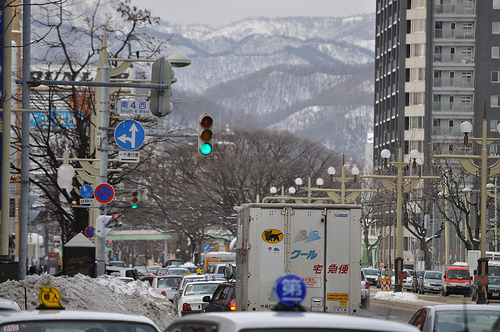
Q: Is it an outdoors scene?
A: Yes, it is outdoors.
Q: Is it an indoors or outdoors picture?
A: It is outdoors.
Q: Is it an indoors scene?
A: No, it is outdoors.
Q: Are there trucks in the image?
A: Yes, there is a truck.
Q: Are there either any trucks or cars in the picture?
A: Yes, there is a truck.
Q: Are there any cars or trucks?
A: Yes, there is a truck.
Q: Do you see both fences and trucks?
A: No, there is a truck but no fences.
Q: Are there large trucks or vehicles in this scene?
A: Yes, there is a large truck.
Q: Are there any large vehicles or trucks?
A: Yes, there is a large truck.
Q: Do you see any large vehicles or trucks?
A: Yes, there is a large truck.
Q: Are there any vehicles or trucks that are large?
A: Yes, the truck is large.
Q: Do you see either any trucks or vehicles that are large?
A: Yes, the truck is large.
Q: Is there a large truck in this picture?
A: Yes, there is a large truck.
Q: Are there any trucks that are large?
A: Yes, there is a truck that is large.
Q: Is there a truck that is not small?
A: Yes, there is a large truck.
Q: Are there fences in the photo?
A: No, there are no fences.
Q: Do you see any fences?
A: No, there are no fences.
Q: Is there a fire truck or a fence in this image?
A: No, there are no fences or fire trucks.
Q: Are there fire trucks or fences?
A: No, there are no fences or fire trucks.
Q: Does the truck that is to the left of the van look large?
A: Yes, the truck is large.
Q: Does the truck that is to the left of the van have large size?
A: Yes, the truck is large.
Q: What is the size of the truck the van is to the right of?
A: The truck is large.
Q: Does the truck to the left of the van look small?
A: No, the truck is large.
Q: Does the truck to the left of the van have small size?
A: No, the truck is large.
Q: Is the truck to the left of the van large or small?
A: The truck is large.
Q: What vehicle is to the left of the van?
A: The vehicle is a truck.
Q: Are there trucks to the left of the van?
A: Yes, there is a truck to the left of the van.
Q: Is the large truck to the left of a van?
A: Yes, the truck is to the left of a van.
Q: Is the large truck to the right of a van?
A: No, the truck is to the left of a van.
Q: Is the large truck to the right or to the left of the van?
A: The truck is to the left of the van.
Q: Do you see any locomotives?
A: No, there are no locomotives.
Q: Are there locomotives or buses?
A: No, there are no locomotives or buses.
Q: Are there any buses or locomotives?
A: No, there are no locomotives or buses.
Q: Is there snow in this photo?
A: Yes, there is snow.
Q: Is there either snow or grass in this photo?
A: Yes, there is snow.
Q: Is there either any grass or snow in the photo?
A: Yes, there is snow.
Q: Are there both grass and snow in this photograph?
A: No, there is snow but no grass.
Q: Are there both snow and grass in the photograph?
A: No, there is snow but no grass.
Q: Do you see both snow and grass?
A: No, there is snow but no grass.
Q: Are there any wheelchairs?
A: No, there are no wheelchairs.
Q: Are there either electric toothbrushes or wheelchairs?
A: No, there are no wheelchairs or electric toothbrushes.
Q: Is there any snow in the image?
A: Yes, there is snow.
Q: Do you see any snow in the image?
A: Yes, there is snow.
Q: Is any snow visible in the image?
A: Yes, there is snow.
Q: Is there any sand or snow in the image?
A: Yes, there is snow.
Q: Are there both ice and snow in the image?
A: No, there is snow but no ice.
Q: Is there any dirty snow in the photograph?
A: Yes, there is dirty snow.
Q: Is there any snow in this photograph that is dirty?
A: Yes, there is snow that is dirty.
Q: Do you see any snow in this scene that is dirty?
A: Yes, there is snow that is dirty.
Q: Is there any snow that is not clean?
A: Yes, there is dirty snow.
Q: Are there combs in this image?
A: No, there are no combs.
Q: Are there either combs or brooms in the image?
A: No, there are no combs or brooms.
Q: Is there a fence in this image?
A: No, there are no fences.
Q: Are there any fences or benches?
A: No, there are no fences or benches.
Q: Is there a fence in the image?
A: No, there are no fences.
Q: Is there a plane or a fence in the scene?
A: No, there are no fences or airplanes.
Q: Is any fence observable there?
A: No, there are no fences.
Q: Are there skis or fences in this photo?
A: No, there are no fences or skis.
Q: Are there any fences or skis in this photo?
A: No, there are no fences or skis.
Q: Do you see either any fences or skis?
A: No, there are no fences or skis.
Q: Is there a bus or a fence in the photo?
A: No, there are no fences or buses.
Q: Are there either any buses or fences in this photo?
A: No, there are no fences or buses.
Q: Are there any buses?
A: No, there are no buses.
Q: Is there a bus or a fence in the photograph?
A: No, there are no buses or fences.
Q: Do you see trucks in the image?
A: Yes, there is a truck.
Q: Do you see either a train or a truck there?
A: Yes, there is a truck.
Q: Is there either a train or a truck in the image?
A: Yes, there is a truck.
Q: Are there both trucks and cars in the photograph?
A: Yes, there are both a truck and a car.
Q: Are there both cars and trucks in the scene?
A: Yes, there are both a truck and a car.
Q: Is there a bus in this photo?
A: No, there are no buses.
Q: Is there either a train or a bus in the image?
A: No, there are no buses or trains.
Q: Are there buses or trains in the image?
A: No, there are no buses or trains.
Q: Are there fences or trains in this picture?
A: No, there are no fences or trains.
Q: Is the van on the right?
A: Yes, the van is on the right of the image.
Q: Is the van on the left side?
A: No, the van is on the right of the image.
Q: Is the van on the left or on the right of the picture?
A: The van is on the right of the image.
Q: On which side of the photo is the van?
A: The van is on the right of the image.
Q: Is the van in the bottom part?
A: Yes, the van is in the bottom of the image.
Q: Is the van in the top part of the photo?
A: No, the van is in the bottom of the image.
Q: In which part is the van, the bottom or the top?
A: The van is in the bottom of the image.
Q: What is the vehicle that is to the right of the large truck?
A: The vehicle is a van.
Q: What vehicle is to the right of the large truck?
A: The vehicle is a van.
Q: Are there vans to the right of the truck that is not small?
A: Yes, there is a van to the right of the truck.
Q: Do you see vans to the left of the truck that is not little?
A: No, the van is to the right of the truck.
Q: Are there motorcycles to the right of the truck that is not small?
A: No, there is a van to the right of the truck.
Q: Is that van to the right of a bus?
A: No, the van is to the right of the truck.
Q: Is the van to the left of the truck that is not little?
A: No, the van is to the right of the truck.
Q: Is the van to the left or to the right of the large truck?
A: The van is to the right of the truck.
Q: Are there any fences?
A: No, there are no fences.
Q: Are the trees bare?
A: Yes, the trees are bare.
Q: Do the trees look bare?
A: Yes, the trees are bare.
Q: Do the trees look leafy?
A: No, the trees are bare.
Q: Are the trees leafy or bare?
A: The trees are bare.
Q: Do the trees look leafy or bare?
A: The trees are bare.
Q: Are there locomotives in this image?
A: No, there are no locomotives.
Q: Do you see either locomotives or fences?
A: No, there are no locomotives or fences.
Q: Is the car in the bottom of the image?
A: Yes, the car is in the bottom of the image.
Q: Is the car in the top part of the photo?
A: No, the car is in the bottom of the image.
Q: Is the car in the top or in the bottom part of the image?
A: The car is in the bottom of the image.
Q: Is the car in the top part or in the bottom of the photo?
A: The car is in the bottom of the image.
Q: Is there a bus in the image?
A: No, there are no buses.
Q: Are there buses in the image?
A: No, there are no buses.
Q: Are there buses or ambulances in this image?
A: No, there are no buses or ambulances.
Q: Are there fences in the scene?
A: No, there are no fences.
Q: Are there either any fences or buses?
A: No, there are no fences or buses.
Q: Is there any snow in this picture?
A: Yes, there is snow.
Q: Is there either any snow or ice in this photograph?
A: Yes, there is snow.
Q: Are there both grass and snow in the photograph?
A: No, there is snow but no grass.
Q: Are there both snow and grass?
A: No, there is snow but no grass.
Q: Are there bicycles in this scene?
A: No, there are no bicycles.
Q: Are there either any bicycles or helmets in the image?
A: No, there are no bicycles or helmets.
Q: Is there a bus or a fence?
A: No, there are no buses or fences.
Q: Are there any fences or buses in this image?
A: No, there are no buses or fences.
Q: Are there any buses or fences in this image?
A: No, there are no buses or fences.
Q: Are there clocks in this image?
A: No, there are no clocks.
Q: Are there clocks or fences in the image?
A: No, there are no clocks or fences.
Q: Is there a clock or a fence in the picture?
A: No, there are no clocks or fences.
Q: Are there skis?
A: No, there are no skis.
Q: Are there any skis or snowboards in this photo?
A: No, there are no skis or snowboards.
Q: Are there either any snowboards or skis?
A: No, there are no skis or snowboards.